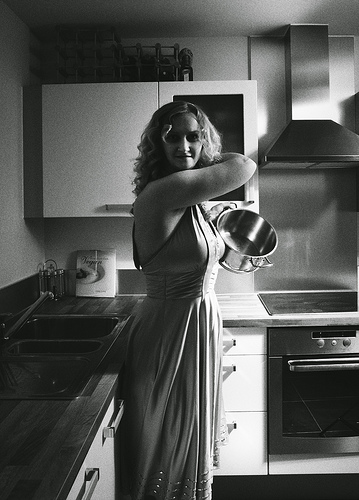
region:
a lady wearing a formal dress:
[83, 93, 290, 473]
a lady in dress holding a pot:
[132, 106, 284, 490]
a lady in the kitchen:
[91, 88, 351, 431]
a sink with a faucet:
[1, 271, 122, 401]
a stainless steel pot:
[212, 200, 281, 283]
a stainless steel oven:
[259, 281, 357, 470]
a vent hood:
[253, 31, 356, 175]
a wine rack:
[42, 22, 192, 92]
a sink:
[14, 310, 113, 350]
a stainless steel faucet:
[1, 284, 54, 347]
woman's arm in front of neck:
[99, 67, 271, 219]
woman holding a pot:
[202, 195, 302, 298]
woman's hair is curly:
[137, 86, 235, 195]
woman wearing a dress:
[103, 190, 233, 497]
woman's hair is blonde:
[119, 77, 215, 170]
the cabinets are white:
[37, 89, 314, 230]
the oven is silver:
[266, 320, 354, 446]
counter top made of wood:
[0, 384, 161, 497]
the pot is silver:
[209, 207, 289, 297]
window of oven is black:
[284, 359, 354, 429]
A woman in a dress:
[131, 96, 234, 490]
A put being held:
[210, 194, 274, 283]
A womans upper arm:
[157, 163, 253, 201]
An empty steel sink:
[12, 306, 84, 405]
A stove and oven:
[267, 287, 354, 453]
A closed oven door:
[264, 330, 357, 454]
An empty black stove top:
[258, 289, 353, 310]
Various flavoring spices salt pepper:
[36, 262, 66, 306]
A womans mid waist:
[140, 270, 221, 326]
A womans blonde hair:
[131, 116, 169, 175]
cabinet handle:
[94, 405, 188, 469]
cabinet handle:
[63, 441, 133, 483]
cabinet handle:
[92, 414, 143, 457]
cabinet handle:
[76, 420, 162, 488]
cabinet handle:
[103, 414, 152, 475]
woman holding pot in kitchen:
[67, 81, 251, 299]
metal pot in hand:
[204, 204, 277, 281]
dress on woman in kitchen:
[93, 192, 224, 445]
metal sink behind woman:
[25, 265, 97, 372]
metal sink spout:
[30, 293, 58, 343]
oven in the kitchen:
[238, 302, 355, 489]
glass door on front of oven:
[263, 371, 346, 452]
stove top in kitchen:
[281, 270, 348, 329]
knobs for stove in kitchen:
[287, 330, 348, 371]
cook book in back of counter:
[59, 232, 121, 316]